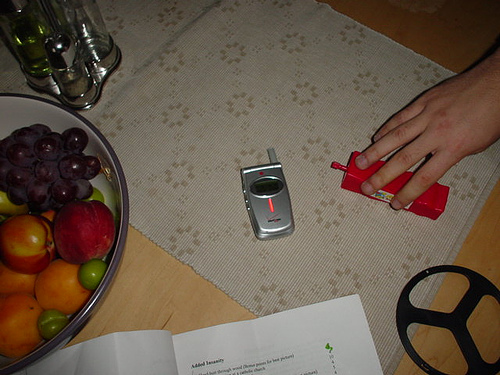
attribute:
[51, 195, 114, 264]
peach — red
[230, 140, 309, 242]
phone — silver, flip, cell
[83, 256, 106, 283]
lime — green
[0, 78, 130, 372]
bowl — fruit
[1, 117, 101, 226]
grapes — black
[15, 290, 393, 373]
book — open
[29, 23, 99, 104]
shaker — glass, pepper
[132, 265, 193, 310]
table — light colored, wooden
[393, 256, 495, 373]
sterring wheel — black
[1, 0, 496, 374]
placemat — cream, colored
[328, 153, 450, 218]
case — red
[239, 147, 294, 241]
cellphone — printed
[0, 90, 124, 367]
bowl — fruit